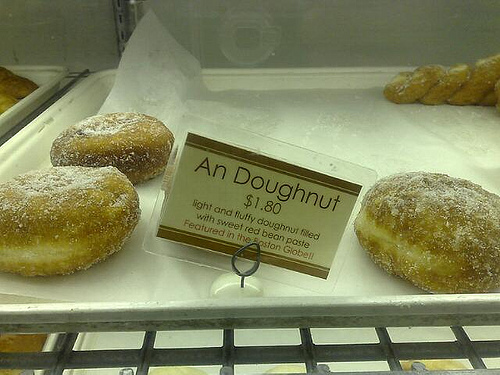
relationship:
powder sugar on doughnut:
[3, 170, 127, 235] [8, 166, 140, 280]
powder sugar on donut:
[34, 170, 69, 189] [10, 167, 141, 279]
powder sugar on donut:
[12, 182, 42, 210] [4, 162, 154, 278]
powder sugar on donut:
[68, 180, 90, 200] [8, 168, 138, 266]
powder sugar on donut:
[68, 174, 101, 201] [1, 168, 138, 278]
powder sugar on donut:
[87, 121, 134, 146] [55, 110, 179, 163]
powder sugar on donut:
[108, 119, 148, 140] [59, 104, 175, 165]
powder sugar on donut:
[385, 194, 467, 213] [354, 164, 484, 285]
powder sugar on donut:
[403, 205, 451, 227] [354, 164, 484, 285]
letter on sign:
[192, 155, 213, 177] [147, 131, 360, 288]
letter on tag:
[208, 155, 233, 176] [150, 123, 366, 283]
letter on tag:
[231, 162, 251, 184] [150, 123, 366, 283]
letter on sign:
[250, 173, 267, 187] [139, 120, 379, 283]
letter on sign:
[273, 178, 290, 213] [152, 123, 365, 285]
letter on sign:
[292, 182, 307, 206] [146, 109, 369, 279]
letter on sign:
[291, 180, 311, 209] [146, 109, 369, 279]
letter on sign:
[319, 191, 333, 214] [146, 109, 369, 279]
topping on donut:
[2, 155, 118, 222] [1, 161, 146, 270]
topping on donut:
[60, 106, 140, 152] [40, 99, 178, 179]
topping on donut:
[379, 150, 497, 260] [358, 167, 495, 319]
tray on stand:
[2, 60, 498, 327] [2, 320, 498, 373]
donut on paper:
[354, 167, 494, 307] [29, 6, 499, 303]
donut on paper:
[2, 153, 154, 293] [29, 6, 499, 303]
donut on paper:
[56, 103, 184, 179] [29, 6, 499, 303]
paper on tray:
[29, 6, 499, 303] [2, 60, 498, 327]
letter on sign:
[260, 178, 278, 198] [127, 100, 389, 300]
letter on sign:
[329, 193, 339, 210] [147, 131, 360, 288]